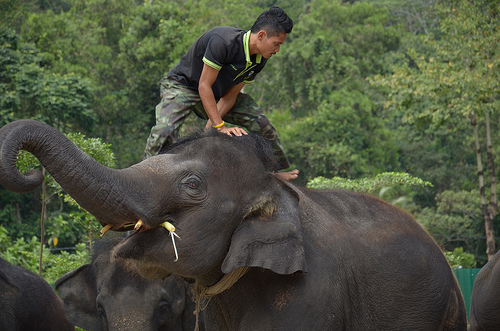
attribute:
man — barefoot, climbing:
[144, 14, 310, 171]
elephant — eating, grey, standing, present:
[5, 115, 472, 330]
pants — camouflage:
[139, 72, 293, 162]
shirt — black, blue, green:
[162, 10, 265, 91]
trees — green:
[4, 2, 499, 199]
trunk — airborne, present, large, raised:
[3, 118, 176, 236]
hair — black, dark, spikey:
[252, 8, 294, 38]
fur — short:
[179, 126, 216, 151]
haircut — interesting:
[270, 5, 289, 24]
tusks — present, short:
[150, 217, 184, 236]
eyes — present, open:
[183, 176, 213, 201]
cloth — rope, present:
[184, 263, 267, 316]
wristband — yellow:
[212, 117, 228, 130]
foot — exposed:
[276, 152, 296, 177]